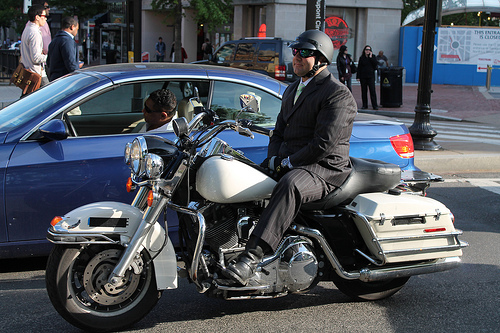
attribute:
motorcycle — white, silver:
[45, 87, 468, 332]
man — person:
[225, 28, 357, 286]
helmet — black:
[289, 26, 335, 63]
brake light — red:
[387, 130, 414, 162]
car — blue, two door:
[0, 63, 429, 264]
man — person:
[129, 88, 178, 132]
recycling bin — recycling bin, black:
[378, 63, 403, 109]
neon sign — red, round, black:
[323, 14, 348, 49]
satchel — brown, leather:
[13, 65, 42, 98]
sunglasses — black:
[290, 46, 319, 58]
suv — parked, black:
[189, 35, 300, 88]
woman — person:
[355, 44, 380, 110]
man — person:
[14, 4, 51, 97]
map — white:
[435, 26, 499, 67]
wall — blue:
[397, 25, 499, 90]